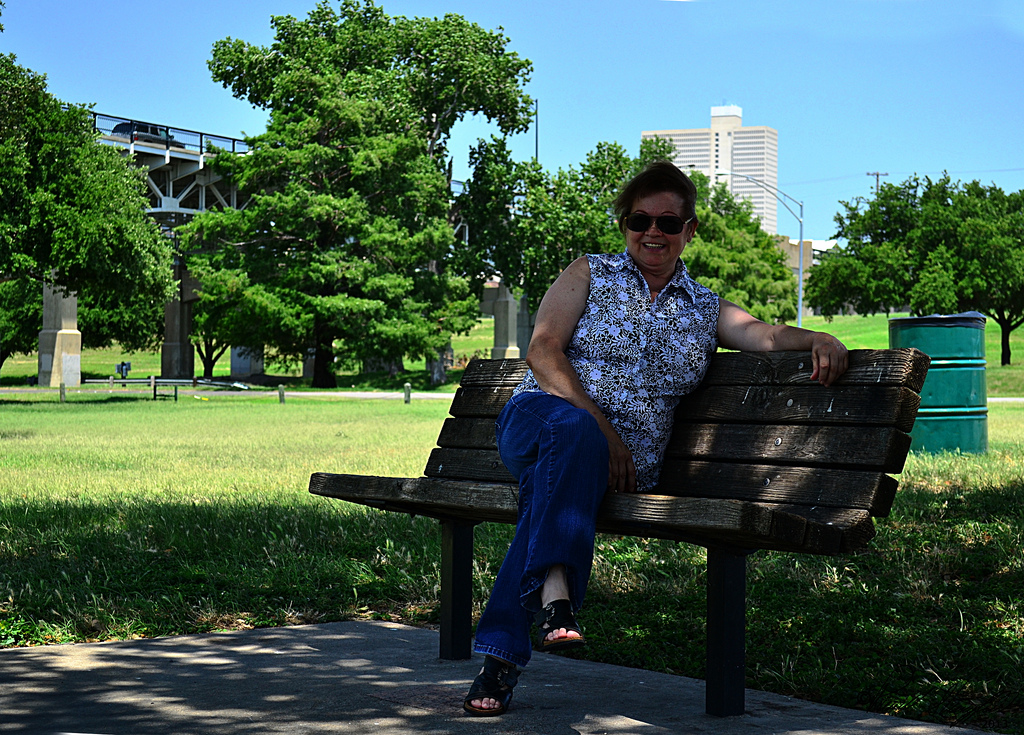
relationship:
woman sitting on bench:
[466, 162, 847, 716] [342, 340, 909, 645]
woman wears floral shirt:
[449, 169, 838, 720] [578, 257, 708, 435]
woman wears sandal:
[449, 169, 838, 720] [517, 586, 597, 643]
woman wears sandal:
[466, 162, 847, 716] [445, 640, 518, 714]